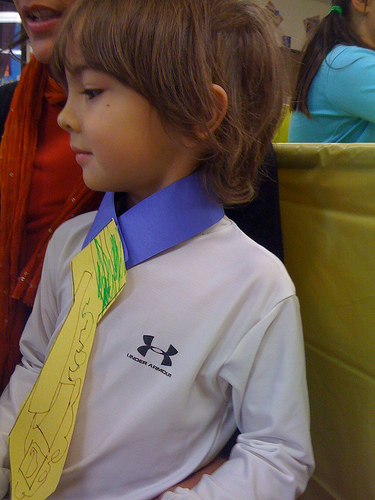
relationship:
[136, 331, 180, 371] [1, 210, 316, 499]
logo on shirt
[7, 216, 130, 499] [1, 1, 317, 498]
tie on boy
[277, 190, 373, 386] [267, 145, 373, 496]
lines on wall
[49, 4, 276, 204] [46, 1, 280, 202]
hair on head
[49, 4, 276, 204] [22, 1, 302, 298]
hair on kid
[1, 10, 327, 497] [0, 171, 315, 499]
boy with shirt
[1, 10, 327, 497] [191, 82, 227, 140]
boy in ear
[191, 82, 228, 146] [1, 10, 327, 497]
ear on boy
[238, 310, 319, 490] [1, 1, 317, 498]
arm of boy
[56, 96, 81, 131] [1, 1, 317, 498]
nose of boy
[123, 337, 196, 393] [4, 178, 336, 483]
logo on shirt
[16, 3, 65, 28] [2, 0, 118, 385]
lips on woman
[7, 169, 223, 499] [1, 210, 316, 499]
tie on shirt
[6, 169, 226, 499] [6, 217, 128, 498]
paper like tie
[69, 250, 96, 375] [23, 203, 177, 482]
drawing on tie